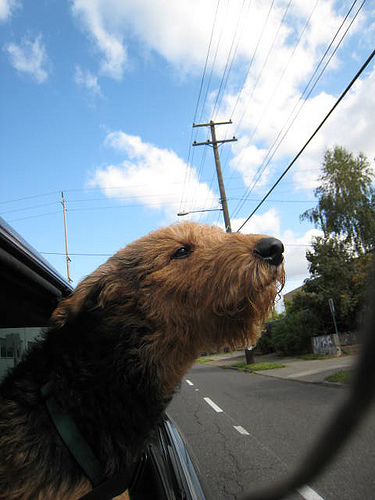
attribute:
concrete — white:
[267, 336, 340, 431]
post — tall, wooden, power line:
[210, 157, 313, 339]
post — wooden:
[58, 191, 73, 286]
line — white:
[183, 376, 196, 388]